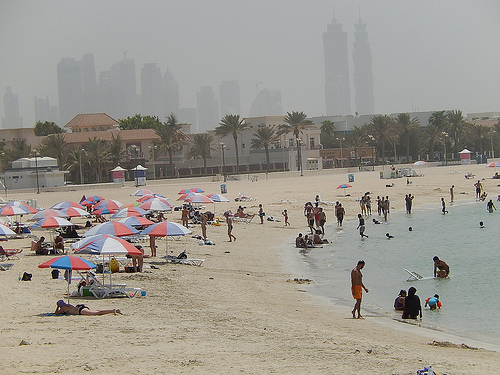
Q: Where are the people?
A: On the beach.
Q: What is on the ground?
A: Umbrellas are on the ground.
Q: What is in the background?
A: Buildings are in the background.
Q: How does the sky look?
A: It is hazy and gray.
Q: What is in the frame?
A: City buildings.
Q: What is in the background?
A: Buildings and palm trees.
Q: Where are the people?
A: In shallow water.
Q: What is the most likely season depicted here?
A: Summer.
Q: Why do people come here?
A: For a relaxing vacation.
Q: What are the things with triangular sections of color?
A: Beach umbrellas.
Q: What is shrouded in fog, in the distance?
A: A city skyline.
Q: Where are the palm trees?
A: Fronting some buildings, just off the beach.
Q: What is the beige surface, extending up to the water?
A: Sand.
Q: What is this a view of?
A: A beach in summertime.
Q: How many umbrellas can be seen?
A: Twenty two.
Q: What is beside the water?
A: Sand.